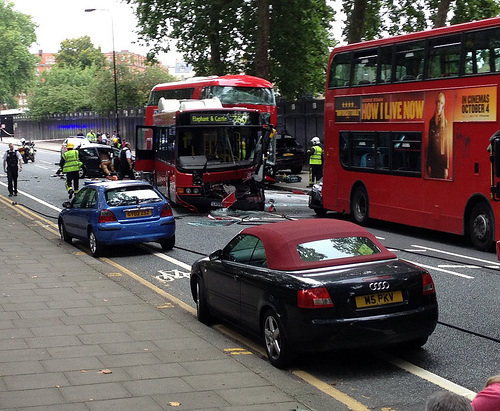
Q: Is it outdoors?
A: Yes, it is outdoors.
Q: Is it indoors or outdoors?
A: It is outdoors.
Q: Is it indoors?
A: No, it is outdoors.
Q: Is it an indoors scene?
A: No, it is outdoors.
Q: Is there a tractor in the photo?
A: No, there are no tractors.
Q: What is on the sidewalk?
A: The car is on the sidewalk.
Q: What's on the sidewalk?
A: The car is on the sidewalk.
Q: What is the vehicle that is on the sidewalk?
A: The vehicle is a car.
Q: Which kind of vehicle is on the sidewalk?
A: The vehicle is a car.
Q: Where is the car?
A: The car is on the sidewalk.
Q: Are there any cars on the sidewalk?
A: Yes, there is a car on the sidewalk.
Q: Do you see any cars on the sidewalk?
A: Yes, there is a car on the sidewalk.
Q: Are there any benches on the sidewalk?
A: No, there is a car on the sidewalk.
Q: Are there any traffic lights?
A: No, there are no traffic lights.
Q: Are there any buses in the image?
A: Yes, there is a bus.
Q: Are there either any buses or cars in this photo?
A: Yes, there is a bus.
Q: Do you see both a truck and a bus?
A: No, there is a bus but no trucks.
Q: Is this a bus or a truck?
A: This is a bus.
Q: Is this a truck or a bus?
A: This is a bus.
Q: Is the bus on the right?
A: Yes, the bus is on the right of the image.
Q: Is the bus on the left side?
A: No, the bus is on the right of the image.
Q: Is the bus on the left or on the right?
A: The bus is on the right of the image.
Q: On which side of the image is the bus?
A: The bus is on the right of the image.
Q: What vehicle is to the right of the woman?
A: The vehicle is a bus.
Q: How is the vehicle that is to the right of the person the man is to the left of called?
A: The vehicle is a bus.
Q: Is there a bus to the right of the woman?
A: Yes, there is a bus to the right of the woman.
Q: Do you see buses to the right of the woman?
A: Yes, there is a bus to the right of the woman.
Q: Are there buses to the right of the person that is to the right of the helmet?
A: Yes, there is a bus to the right of the woman.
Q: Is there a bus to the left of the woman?
A: No, the bus is to the right of the woman.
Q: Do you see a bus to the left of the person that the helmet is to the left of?
A: No, the bus is to the right of the woman.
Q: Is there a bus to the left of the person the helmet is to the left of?
A: No, the bus is to the right of the woman.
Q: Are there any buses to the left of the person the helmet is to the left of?
A: No, the bus is to the right of the woman.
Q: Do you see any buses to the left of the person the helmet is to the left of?
A: No, the bus is to the right of the woman.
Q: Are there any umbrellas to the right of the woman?
A: No, there is a bus to the right of the woman.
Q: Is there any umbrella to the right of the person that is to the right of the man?
A: No, there is a bus to the right of the woman.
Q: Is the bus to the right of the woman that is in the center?
A: Yes, the bus is to the right of the woman.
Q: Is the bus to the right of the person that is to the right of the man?
A: Yes, the bus is to the right of the woman.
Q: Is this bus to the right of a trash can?
A: No, the bus is to the right of the woman.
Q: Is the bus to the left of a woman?
A: No, the bus is to the right of a woman.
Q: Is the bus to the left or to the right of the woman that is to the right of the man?
A: The bus is to the right of the woman.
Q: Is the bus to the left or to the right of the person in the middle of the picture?
A: The bus is to the right of the woman.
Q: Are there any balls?
A: No, there are no balls.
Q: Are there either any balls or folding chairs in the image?
A: No, there are no balls or folding chairs.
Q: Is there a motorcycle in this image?
A: Yes, there is a motorcycle.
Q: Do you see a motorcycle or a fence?
A: Yes, there is a motorcycle.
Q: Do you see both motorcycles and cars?
A: Yes, there are both a motorcycle and a car.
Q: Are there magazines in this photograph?
A: No, there are no magazines.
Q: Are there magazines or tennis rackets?
A: No, there are no magazines or tennis rackets.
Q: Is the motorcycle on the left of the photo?
A: Yes, the motorcycle is on the left of the image.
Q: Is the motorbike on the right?
A: No, the motorbike is on the left of the image.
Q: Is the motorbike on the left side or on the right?
A: The motorbike is on the left of the image.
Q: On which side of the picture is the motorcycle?
A: The motorcycle is on the left of the image.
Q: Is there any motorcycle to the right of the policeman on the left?
A: Yes, there is a motorcycle to the right of the policeman.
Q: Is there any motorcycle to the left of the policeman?
A: No, the motorcycle is to the right of the policeman.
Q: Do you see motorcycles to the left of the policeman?
A: No, the motorcycle is to the right of the policeman.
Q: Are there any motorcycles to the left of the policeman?
A: No, the motorcycle is to the right of the policeman.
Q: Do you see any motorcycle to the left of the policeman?
A: No, the motorcycle is to the right of the policeman.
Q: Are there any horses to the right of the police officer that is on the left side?
A: No, there is a motorcycle to the right of the policeman.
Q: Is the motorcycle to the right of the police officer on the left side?
A: Yes, the motorcycle is to the right of the police officer.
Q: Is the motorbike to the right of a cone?
A: No, the motorbike is to the right of the police officer.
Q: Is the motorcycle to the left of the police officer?
A: No, the motorcycle is to the right of the police officer.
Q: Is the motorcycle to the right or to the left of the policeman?
A: The motorcycle is to the right of the policeman.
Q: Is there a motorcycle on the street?
A: Yes, there is a motorcycle on the street.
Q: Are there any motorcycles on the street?
A: Yes, there is a motorcycle on the street.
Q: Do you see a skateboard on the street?
A: No, there is a motorcycle on the street.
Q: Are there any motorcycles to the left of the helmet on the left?
A: Yes, there is a motorcycle to the left of the helmet.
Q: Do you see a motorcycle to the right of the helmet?
A: No, the motorcycle is to the left of the helmet.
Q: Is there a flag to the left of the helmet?
A: No, there is a motorcycle to the left of the helmet.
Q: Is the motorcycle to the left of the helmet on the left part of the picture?
A: Yes, the motorcycle is to the left of the helmet.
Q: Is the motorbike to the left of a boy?
A: No, the motorbike is to the left of the helmet.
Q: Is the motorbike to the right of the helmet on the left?
A: No, the motorbike is to the left of the helmet.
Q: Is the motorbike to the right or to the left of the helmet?
A: The motorbike is to the left of the helmet.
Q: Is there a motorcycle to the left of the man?
A: Yes, there is a motorcycle to the left of the man.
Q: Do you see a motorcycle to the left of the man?
A: Yes, there is a motorcycle to the left of the man.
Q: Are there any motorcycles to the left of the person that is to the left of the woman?
A: Yes, there is a motorcycle to the left of the man.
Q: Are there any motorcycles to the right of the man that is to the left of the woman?
A: No, the motorcycle is to the left of the man.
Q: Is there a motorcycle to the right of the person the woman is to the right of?
A: No, the motorcycle is to the left of the man.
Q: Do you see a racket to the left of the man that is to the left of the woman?
A: No, there is a motorcycle to the left of the man.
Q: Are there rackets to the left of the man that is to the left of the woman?
A: No, there is a motorcycle to the left of the man.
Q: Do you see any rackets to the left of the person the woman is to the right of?
A: No, there is a motorcycle to the left of the man.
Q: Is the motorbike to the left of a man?
A: Yes, the motorbike is to the left of a man.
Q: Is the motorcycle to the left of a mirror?
A: No, the motorcycle is to the left of a man.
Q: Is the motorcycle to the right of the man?
A: No, the motorcycle is to the left of the man.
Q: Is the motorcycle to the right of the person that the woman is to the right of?
A: No, the motorcycle is to the left of the man.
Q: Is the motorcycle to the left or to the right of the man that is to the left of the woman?
A: The motorcycle is to the left of the man.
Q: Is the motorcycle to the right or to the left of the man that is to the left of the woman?
A: The motorcycle is to the left of the man.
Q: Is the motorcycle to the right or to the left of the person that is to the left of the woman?
A: The motorcycle is to the left of the man.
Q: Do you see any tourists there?
A: No, there are no tourists.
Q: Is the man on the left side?
A: Yes, the man is on the left of the image.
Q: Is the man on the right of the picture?
A: No, the man is on the left of the image.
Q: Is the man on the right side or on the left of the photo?
A: The man is on the left of the image.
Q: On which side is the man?
A: The man is on the left of the image.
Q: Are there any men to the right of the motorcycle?
A: Yes, there is a man to the right of the motorcycle.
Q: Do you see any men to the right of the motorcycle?
A: Yes, there is a man to the right of the motorcycle.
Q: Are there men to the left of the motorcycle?
A: No, the man is to the right of the motorcycle.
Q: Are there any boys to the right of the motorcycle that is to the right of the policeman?
A: No, there is a man to the right of the motorbike.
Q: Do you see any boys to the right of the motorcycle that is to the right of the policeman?
A: No, there is a man to the right of the motorbike.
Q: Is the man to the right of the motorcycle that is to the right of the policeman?
A: Yes, the man is to the right of the motorcycle.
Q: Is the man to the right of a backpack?
A: No, the man is to the right of the motorcycle.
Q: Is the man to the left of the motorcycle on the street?
A: No, the man is to the right of the motorbike.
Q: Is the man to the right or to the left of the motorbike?
A: The man is to the right of the motorbike.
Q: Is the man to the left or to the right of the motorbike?
A: The man is to the right of the motorbike.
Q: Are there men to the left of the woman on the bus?
A: Yes, there is a man to the left of the woman.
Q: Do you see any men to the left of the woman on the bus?
A: Yes, there is a man to the left of the woman.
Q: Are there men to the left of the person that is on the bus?
A: Yes, there is a man to the left of the woman.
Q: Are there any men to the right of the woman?
A: No, the man is to the left of the woman.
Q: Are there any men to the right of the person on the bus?
A: No, the man is to the left of the woman.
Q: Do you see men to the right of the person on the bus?
A: No, the man is to the left of the woman.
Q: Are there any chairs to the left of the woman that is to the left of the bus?
A: No, there is a man to the left of the woman.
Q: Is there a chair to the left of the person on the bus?
A: No, there is a man to the left of the woman.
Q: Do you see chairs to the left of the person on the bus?
A: No, there is a man to the left of the woman.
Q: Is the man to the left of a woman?
A: Yes, the man is to the left of a woman.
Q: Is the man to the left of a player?
A: No, the man is to the left of a woman.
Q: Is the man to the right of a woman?
A: No, the man is to the left of a woman.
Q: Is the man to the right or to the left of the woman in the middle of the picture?
A: The man is to the left of the woman.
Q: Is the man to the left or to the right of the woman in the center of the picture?
A: The man is to the left of the woman.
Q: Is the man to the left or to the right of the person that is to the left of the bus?
A: The man is to the left of the woman.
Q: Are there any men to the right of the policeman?
A: Yes, there is a man to the right of the policeman.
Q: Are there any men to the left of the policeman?
A: No, the man is to the right of the policeman.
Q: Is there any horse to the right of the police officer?
A: No, there is a man to the right of the police officer.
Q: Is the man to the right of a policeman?
A: Yes, the man is to the right of a policeman.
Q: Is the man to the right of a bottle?
A: No, the man is to the right of a policeman.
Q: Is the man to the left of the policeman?
A: No, the man is to the right of the policeman.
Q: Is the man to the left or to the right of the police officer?
A: The man is to the right of the police officer.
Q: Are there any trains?
A: No, there are no trains.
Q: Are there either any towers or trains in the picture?
A: No, there are no trains or towers.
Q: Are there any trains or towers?
A: No, there are no trains or towers.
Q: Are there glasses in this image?
A: No, there are no glasses.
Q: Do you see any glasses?
A: No, there are no glasses.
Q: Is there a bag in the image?
A: No, there are no bags.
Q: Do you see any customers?
A: No, there are no customers.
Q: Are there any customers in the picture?
A: No, there are no customers.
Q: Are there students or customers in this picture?
A: No, there are no customers or students.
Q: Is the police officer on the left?
A: Yes, the police officer is on the left of the image.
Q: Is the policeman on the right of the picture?
A: No, the policeman is on the left of the image.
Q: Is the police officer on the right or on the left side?
A: The police officer is on the left of the image.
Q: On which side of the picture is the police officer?
A: The police officer is on the left of the image.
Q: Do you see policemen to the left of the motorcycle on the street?
A: Yes, there is a policeman to the left of the motorcycle.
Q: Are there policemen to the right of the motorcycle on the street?
A: No, the policeman is to the left of the motorbike.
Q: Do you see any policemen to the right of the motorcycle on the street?
A: No, the policeman is to the left of the motorbike.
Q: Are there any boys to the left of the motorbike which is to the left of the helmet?
A: No, there is a policeman to the left of the motorbike.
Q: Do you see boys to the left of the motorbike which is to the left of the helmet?
A: No, there is a policeman to the left of the motorbike.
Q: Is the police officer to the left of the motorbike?
A: Yes, the police officer is to the left of the motorbike.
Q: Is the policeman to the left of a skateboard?
A: No, the policeman is to the left of the motorbike.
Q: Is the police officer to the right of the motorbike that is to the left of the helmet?
A: No, the police officer is to the left of the motorcycle.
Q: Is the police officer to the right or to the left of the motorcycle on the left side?
A: The police officer is to the left of the motorbike.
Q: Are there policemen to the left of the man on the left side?
A: Yes, there is a policeman to the left of the man.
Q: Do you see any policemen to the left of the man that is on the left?
A: Yes, there is a policeman to the left of the man.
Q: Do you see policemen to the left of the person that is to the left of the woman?
A: Yes, there is a policeman to the left of the man.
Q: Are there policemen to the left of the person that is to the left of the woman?
A: Yes, there is a policeman to the left of the man.